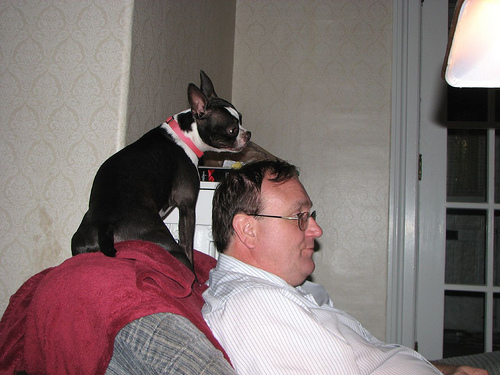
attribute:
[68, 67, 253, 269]
dog — black, white, small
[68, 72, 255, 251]
fur — black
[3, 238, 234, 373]
blanket — red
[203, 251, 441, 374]
shirt — white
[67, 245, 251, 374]
chair — gray, bluish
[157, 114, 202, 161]
collar — pink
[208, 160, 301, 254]
hair — dark, brown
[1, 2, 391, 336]
wall — printed, white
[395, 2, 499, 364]
door frame — white